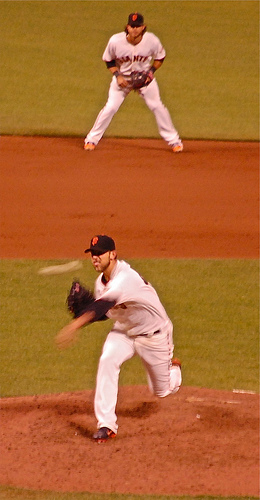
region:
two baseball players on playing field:
[2, 0, 252, 492]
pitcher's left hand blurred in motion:
[48, 270, 165, 348]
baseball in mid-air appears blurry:
[27, 250, 80, 277]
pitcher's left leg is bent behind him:
[143, 338, 182, 403]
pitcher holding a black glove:
[57, 274, 97, 316]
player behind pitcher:
[65, 1, 188, 317]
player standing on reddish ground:
[6, 134, 253, 225]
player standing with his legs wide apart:
[72, 3, 191, 166]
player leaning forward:
[102, 9, 161, 87]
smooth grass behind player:
[7, 3, 248, 133]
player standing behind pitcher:
[65, 7, 202, 161]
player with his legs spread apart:
[71, 6, 198, 163]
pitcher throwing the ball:
[52, 227, 220, 459]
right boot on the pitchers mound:
[83, 419, 129, 446]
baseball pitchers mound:
[1, 396, 258, 497]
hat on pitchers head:
[78, 233, 121, 251]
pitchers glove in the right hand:
[60, 274, 106, 324]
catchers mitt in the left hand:
[130, 68, 156, 92]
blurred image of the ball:
[31, 256, 90, 276]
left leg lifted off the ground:
[135, 330, 191, 408]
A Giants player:
[78, 5, 182, 149]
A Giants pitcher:
[53, 215, 199, 450]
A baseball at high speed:
[10, 240, 81, 281]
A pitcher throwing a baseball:
[34, 205, 203, 452]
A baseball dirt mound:
[8, 367, 242, 493]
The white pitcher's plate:
[172, 351, 246, 436]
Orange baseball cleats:
[54, 117, 210, 182]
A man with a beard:
[54, 216, 149, 328]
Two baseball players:
[35, 6, 201, 397]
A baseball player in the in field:
[61, 8, 256, 154]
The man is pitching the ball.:
[74, 234, 199, 409]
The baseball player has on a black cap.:
[83, 228, 127, 254]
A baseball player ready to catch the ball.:
[81, 23, 197, 159]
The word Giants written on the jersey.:
[112, 47, 162, 72]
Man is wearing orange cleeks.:
[72, 133, 129, 156]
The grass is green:
[190, 275, 243, 350]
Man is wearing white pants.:
[97, 329, 176, 404]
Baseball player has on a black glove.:
[57, 280, 94, 320]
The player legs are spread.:
[99, 20, 176, 154]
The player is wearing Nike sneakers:
[89, 421, 122, 451]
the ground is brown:
[70, 154, 257, 208]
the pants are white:
[77, 367, 128, 423]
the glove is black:
[61, 284, 107, 310]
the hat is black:
[80, 233, 122, 253]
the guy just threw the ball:
[54, 242, 214, 398]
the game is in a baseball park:
[1, 212, 258, 498]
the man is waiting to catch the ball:
[86, 18, 210, 151]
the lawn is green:
[199, 310, 256, 375]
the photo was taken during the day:
[0, 138, 257, 497]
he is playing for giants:
[112, 50, 163, 73]